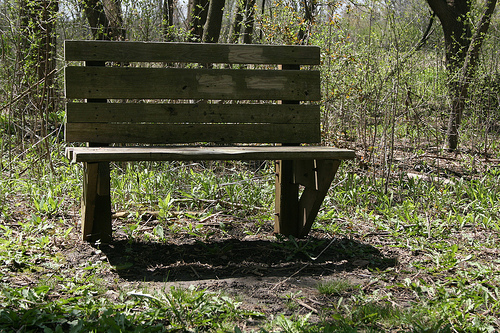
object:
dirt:
[19, 200, 479, 314]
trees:
[424, 0, 495, 152]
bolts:
[269, 209, 280, 217]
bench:
[65, 39, 357, 244]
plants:
[1, 143, 496, 331]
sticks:
[268, 217, 335, 290]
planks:
[57, 40, 324, 66]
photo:
[2, 3, 499, 331]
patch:
[165, 221, 259, 297]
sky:
[57, 0, 409, 34]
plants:
[428, 33, 446, 182]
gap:
[182, 52, 231, 78]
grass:
[0, 279, 263, 331]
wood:
[60, 66, 321, 102]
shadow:
[93, 235, 399, 279]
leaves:
[29, 31, 46, 44]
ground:
[0, 158, 498, 330]